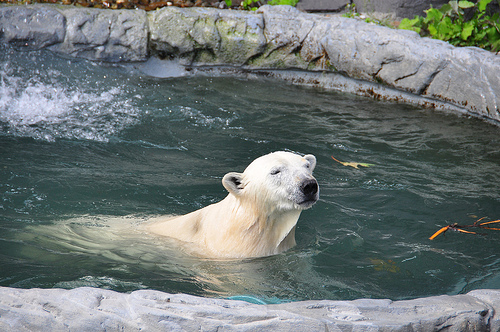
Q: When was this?
A: Daytime.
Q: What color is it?
A: White.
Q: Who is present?
A: Nobody.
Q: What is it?
A: A bear.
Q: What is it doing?
A: Swimming.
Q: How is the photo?
A: Clear.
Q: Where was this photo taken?
A: Near the polar bear.